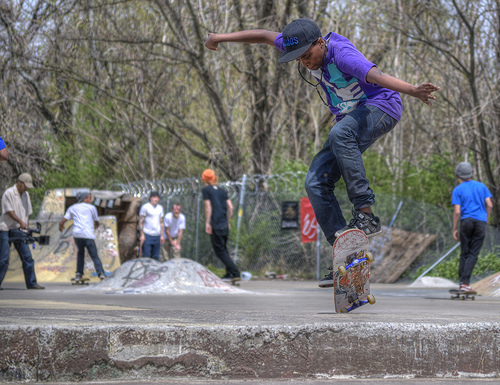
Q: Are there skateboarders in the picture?
A: Yes, there is a skateboarder.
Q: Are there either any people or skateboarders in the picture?
A: Yes, there is a skateboarder.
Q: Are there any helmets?
A: No, there are no helmets.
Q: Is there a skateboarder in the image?
A: Yes, there is a skateboarder.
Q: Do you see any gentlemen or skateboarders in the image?
A: Yes, there is a skateboarder.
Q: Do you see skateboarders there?
A: Yes, there is a skateboarder.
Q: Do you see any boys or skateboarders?
A: Yes, there is a skateboarder.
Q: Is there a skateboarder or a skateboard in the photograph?
A: Yes, there is a skateboarder.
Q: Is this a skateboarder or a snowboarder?
A: This is a skateboarder.